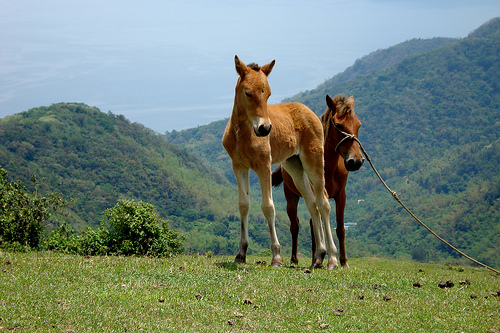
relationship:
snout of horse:
[247, 109, 275, 141] [220, 47, 343, 273]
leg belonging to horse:
[230, 159, 254, 264] [220, 47, 343, 273]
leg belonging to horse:
[253, 162, 283, 269] [220, 47, 343, 273]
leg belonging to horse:
[284, 164, 325, 269] [220, 47, 343, 273]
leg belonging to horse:
[300, 149, 340, 271] [220, 47, 343, 273]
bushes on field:
[0, 181, 180, 257] [1, 252, 494, 333]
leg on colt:
[300, 149, 341, 272] [219, 53, 337, 270]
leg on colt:
[284, 164, 327, 270] [219, 53, 337, 270]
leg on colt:
[230, 159, 254, 264] [219, 53, 337, 270]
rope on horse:
[336, 130, 498, 272] [209, 53, 330, 268]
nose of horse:
[257, 122, 272, 137] [224, 52, 337, 265]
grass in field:
[0, 248, 498, 333] [129, 272, 265, 322]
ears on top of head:
[220, 48, 282, 81] [231, 54, 278, 138]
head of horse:
[231, 54, 278, 138] [220, 47, 343, 273]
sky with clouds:
[3, 5, 498, 137] [2, 5, 495, 127]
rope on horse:
[336, 130, 498, 272] [270, 90, 360, 267]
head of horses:
[225, 54, 281, 140] [225, 43, 365, 171]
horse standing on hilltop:
[209, 53, 330, 268] [1, 12, 499, 262]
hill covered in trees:
[367, 43, 497, 240] [347, 38, 494, 265]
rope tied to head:
[360, 141, 488, 269] [325, 95, 362, 164]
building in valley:
[342, 214, 366, 234] [345, 191, 427, 269]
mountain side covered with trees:
[6, 96, 220, 220] [27, 137, 166, 191]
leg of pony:
[219, 157, 259, 273] [208, 50, 355, 280]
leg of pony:
[253, 162, 292, 270] [208, 50, 355, 280]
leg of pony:
[300, 149, 341, 272] [208, 50, 355, 280]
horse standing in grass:
[209, 53, 330, 268] [19, 256, 493, 319]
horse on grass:
[322, 93, 377, 255] [12, 270, 152, 330]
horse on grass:
[209, 53, 330, 268] [12, 270, 152, 330]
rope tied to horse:
[336, 130, 498, 272] [319, 95, 386, 292]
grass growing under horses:
[76, 256, 492, 326] [175, 67, 427, 269]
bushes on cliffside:
[0, 165, 180, 256] [11, 227, 241, 270]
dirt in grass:
[398, 262, 488, 314] [8, 229, 460, 327]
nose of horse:
[342, 154, 371, 166] [271, 88, 368, 265]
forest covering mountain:
[219, 26, 496, 273] [162, 2, 497, 272]